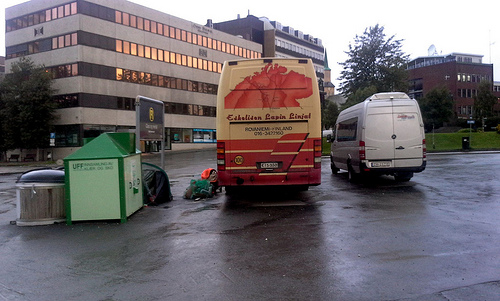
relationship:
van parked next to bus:
[331, 88, 427, 176] [220, 46, 326, 204]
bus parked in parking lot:
[220, 46, 326, 204] [8, 150, 500, 301]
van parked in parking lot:
[331, 88, 427, 176] [8, 150, 500, 301]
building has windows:
[0, 1, 264, 148] [8, 6, 227, 113]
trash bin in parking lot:
[64, 132, 148, 221] [8, 150, 500, 301]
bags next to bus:
[184, 170, 217, 201] [220, 46, 326, 204]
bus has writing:
[220, 46, 326, 204] [225, 112, 308, 134]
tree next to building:
[4, 60, 58, 156] [0, 1, 264, 148]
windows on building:
[8, 6, 227, 113] [0, 1, 264, 148]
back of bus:
[219, 62, 319, 184] [220, 46, 326, 204]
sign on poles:
[139, 103, 162, 138] [133, 97, 170, 171]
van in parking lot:
[331, 88, 427, 176] [8, 150, 500, 301]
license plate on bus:
[262, 162, 280, 171] [220, 46, 326, 204]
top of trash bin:
[70, 132, 140, 157] [64, 132, 148, 221]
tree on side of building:
[4, 60, 58, 156] [0, 1, 264, 148]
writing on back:
[225, 112, 308, 134] [219, 62, 319, 184]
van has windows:
[331, 88, 427, 176] [333, 116, 357, 144]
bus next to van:
[220, 46, 326, 204] [331, 88, 427, 176]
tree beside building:
[4, 60, 58, 156] [0, 1, 264, 148]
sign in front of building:
[139, 103, 162, 138] [0, 1, 264, 148]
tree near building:
[4, 60, 58, 156] [0, 1, 264, 148]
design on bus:
[225, 68, 309, 110] [220, 46, 326, 204]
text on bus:
[243, 125, 296, 137] [220, 46, 326, 204]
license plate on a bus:
[262, 162, 280, 171] [220, 46, 326, 204]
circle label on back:
[234, 152, 247, 164] [219, 62, 319, 184]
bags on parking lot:
[184, 170, 217, 201] [8, 150, 500, 301]